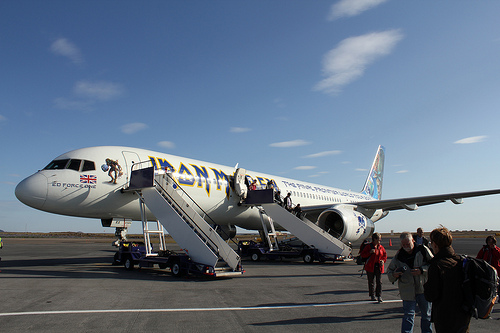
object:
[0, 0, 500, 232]
sky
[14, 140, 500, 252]
plane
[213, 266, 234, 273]
steps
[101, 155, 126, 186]
logo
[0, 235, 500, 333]
ground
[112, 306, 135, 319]
line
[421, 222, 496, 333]
people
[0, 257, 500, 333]
road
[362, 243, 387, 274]
jacket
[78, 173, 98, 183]
flag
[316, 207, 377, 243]
engine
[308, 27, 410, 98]
cloud